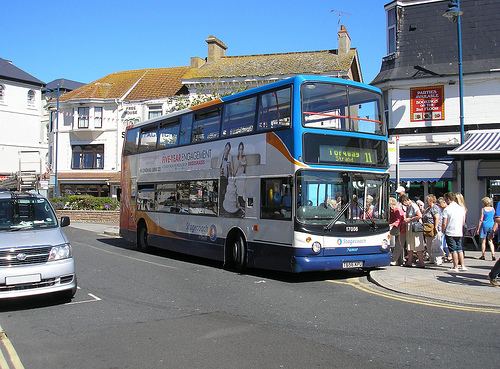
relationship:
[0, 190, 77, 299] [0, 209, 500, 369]
car parked on ground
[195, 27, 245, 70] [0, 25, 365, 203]
chimney on top of buildings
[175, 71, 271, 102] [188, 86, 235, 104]
ivy on wall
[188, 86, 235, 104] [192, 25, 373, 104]
wall of house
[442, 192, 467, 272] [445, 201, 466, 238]
man wearing shirt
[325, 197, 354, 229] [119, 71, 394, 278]
wiper on bus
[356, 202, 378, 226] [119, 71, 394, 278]
wiper on bus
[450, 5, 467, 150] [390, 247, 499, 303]
post on sidewalk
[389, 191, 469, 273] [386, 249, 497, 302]
people on sidewalk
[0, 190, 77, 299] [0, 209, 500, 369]
car on ground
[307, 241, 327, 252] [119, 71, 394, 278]
light on bus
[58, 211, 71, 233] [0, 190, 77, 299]
mirror on car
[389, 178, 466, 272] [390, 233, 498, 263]
people at stop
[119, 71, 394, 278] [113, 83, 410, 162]
bus has level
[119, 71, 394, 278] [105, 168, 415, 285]
bus has level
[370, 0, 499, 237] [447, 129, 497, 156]
building with awning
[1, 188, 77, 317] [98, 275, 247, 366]
car parked on street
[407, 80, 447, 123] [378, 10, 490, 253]
sign on building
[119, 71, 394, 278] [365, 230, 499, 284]
bus stopped at bus stop